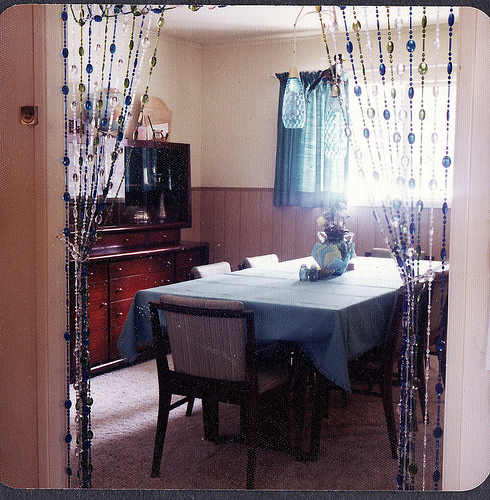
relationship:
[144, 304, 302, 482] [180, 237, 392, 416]
chair near table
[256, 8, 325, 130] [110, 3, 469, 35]
light fixture hanging from ceiling